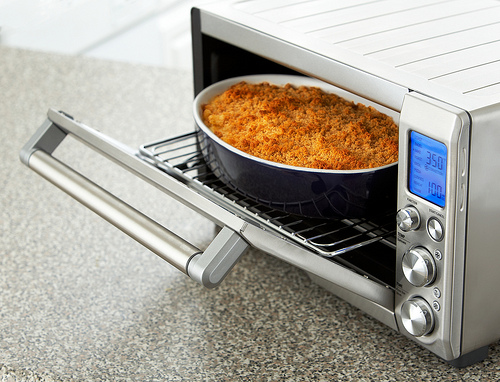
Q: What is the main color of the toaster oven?
A: Silver.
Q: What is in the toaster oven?
A: Dish of food.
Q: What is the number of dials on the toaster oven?
A: 3.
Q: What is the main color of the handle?
A: Silver.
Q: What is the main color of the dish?
A: Black.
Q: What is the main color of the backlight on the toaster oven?
A: Blue.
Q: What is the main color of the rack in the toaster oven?
A: Silver.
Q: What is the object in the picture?
A: Microwave.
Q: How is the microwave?
A: Open.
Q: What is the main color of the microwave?
A: Silver.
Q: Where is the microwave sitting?
A: On a counter.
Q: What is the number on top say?
A: 350.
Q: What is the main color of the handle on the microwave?
A: Silver.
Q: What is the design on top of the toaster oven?
A: Grooved.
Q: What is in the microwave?
A: Bowl of food.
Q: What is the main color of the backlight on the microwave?
A: Blue.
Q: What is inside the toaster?
A: A food.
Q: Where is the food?
A: In a bowl.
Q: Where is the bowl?
A: Inside the toaster.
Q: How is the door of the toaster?
A: Partially open.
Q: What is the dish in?
A: Toaster oven.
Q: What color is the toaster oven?
A: Silver.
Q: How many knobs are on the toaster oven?
A: 3.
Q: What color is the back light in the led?
A: Blue.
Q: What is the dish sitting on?
A: Rack.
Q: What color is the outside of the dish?
A: Royal blue.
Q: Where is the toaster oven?
A: Counter.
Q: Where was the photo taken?
A: In a kitchen.